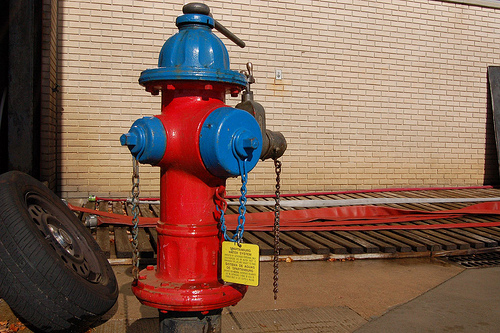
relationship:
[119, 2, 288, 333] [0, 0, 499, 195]
hydrant in front of building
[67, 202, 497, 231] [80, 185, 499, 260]
hose on pallet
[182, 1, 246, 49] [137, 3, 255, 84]
wrench on top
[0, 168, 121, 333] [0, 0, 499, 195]
tire laying against building